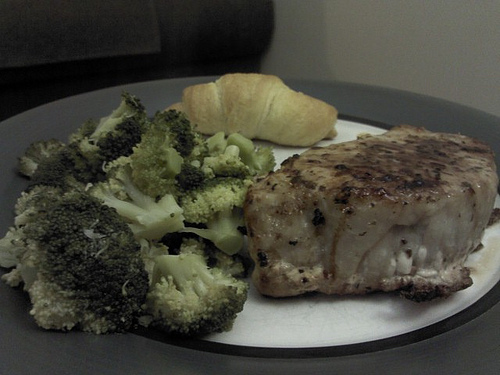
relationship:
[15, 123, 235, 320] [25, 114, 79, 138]
broccoli on plate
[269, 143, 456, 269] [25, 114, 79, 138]
meat on plate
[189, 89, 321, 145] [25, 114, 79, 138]
croissant on plate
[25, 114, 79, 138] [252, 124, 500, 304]
plate of meat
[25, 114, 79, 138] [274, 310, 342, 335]
plate has center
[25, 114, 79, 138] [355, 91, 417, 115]
plate has rim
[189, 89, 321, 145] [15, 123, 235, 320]
croissant by broccoli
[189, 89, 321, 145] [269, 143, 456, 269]
croissant by meat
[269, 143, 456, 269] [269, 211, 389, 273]
meat has fat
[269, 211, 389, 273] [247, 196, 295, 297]
fat on edge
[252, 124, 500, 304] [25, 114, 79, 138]
meat on plate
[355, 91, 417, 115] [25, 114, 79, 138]
rim of plate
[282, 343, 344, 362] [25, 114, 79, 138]
band on plate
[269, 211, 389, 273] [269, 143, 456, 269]
fat on meat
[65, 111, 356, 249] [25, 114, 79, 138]
food types on plate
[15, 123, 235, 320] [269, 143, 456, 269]
broccoli touching meat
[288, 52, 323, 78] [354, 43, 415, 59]
shadow on wall